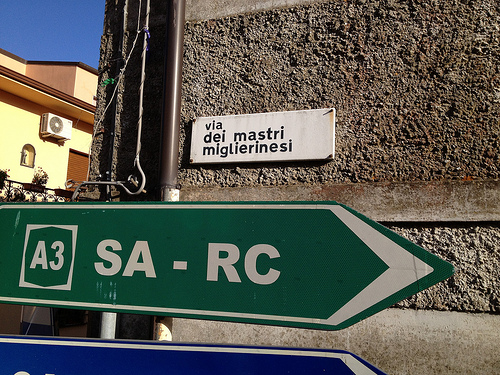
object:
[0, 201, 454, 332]
sign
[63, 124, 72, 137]
white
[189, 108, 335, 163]
white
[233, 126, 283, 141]
words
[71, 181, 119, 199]
metal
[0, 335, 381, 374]
blue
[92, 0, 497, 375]
wall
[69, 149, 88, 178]
wooden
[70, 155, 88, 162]
slats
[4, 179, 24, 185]
railing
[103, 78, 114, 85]
green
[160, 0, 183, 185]
pipe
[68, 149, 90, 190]
door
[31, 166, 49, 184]
plant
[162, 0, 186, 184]
brown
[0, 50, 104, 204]
building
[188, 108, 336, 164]
sign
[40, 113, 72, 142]
unit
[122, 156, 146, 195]
hook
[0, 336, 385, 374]
sign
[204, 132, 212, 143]
letters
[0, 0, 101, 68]
sky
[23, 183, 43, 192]
planter